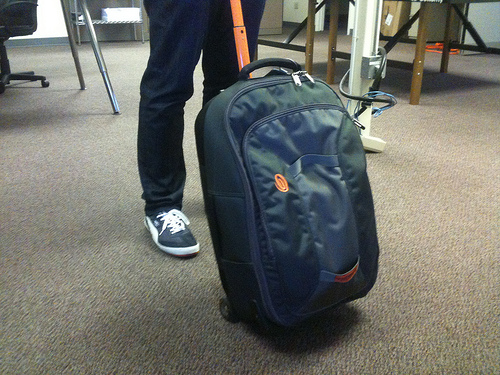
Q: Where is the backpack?
A: On the floor.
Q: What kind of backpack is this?
A: Rolling.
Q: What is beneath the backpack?
A: A grey carpet.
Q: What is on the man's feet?
A: Shoes.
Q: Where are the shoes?
A: On the man's feet.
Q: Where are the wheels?
A: On the backpack.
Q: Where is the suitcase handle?
A: Top of suitcase.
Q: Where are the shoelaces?
A: On the shoes.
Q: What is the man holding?
A: Luggage.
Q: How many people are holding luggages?
A: One.